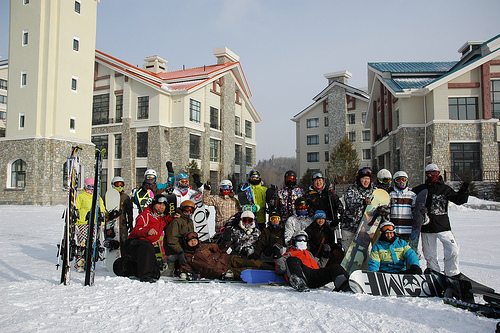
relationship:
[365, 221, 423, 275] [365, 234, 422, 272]
guy in coat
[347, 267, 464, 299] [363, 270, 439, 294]
snowboard with writing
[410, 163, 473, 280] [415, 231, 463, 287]
guy wearing pants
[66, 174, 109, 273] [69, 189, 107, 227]
person wearing coat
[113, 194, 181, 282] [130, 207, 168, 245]
guy wearing coat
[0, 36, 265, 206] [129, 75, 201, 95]
building with roof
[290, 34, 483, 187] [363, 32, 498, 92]
building with roof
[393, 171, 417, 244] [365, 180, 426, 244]
guy wearing shirt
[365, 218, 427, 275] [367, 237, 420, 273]
guy wearing coat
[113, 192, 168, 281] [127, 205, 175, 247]
guy wearing coat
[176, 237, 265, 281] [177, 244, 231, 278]
guy wearing coat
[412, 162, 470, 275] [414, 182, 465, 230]
guy wearing jacket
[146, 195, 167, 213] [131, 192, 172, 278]
head of man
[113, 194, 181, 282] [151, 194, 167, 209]
guy wearing hat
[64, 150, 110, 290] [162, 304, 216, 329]
ski in snow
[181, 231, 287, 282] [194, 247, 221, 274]
guy wearing coat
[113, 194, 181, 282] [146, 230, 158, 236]
guy has hand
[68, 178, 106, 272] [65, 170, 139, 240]
person wearing jacket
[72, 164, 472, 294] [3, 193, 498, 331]
group in snow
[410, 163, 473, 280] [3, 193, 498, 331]
guy in snow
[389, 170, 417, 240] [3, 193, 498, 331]
guy in snow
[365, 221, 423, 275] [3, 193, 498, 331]
guy in snow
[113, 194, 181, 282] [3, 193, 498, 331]
guy in snow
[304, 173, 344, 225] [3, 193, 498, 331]
person in snow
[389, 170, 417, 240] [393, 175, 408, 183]
guy wearing goggles